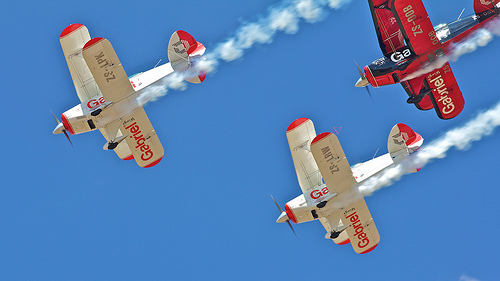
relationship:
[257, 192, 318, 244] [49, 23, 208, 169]
propeller on airplane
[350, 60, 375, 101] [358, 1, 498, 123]
propeller on plane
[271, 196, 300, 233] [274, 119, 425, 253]
propeller on plane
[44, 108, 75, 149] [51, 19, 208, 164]
propeller on plane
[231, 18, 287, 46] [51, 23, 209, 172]
smoke coming from airplane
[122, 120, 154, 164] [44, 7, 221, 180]
writing on bottom of airplane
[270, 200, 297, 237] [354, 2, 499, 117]
propeller of airplane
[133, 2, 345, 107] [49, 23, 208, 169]
smoke of airplane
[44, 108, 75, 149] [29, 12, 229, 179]
propeller on plane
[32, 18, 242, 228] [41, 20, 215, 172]
branding on airplane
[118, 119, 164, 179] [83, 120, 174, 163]
writing under wing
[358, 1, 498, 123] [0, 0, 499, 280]
plane against sky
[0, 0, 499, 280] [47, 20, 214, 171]
sky behind plane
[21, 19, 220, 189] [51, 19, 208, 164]
contrails from plane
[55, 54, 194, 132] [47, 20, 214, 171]
body of plane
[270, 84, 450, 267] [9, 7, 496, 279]
plane in air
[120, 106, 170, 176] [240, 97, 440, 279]
branding on airplane